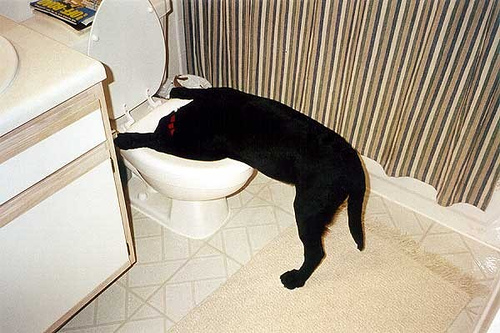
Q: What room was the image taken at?
A: It was taken at the bathroom.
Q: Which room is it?
A: It is a bathroom.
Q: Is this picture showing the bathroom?
A: Yes, it is showing the bathroom.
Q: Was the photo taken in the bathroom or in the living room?
A: It was taken at the bathroom.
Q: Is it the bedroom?
A: No, it is the bathroom.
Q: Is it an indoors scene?
A: Yes, it is indoors.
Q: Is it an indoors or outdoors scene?
A: It is indoors.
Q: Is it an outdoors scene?
A: No, it is indoors.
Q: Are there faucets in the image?
A: No, there are no faucets.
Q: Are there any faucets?
A: No, there are no faucets.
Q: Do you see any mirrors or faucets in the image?
A: No, there are no faucets or mirrors.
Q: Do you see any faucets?
A: No, there are no faucets.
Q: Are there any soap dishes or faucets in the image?
A: No, there are no faucets or soap dishes.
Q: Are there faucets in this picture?
A: No, there are no faucets.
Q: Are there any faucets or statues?
A: No, there are no faucets or statues.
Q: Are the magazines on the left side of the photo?
A: Yes, the magazines are on the left of the image.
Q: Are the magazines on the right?
A: No, the magazines are on the left of the image.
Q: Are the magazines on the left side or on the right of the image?
A: The magazines are on the left of the image.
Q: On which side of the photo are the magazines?
A: The magazines are on the left of the image.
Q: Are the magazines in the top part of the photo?
A: Yes, the magazines are in the top of the image.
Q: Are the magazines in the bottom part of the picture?
A: No, the magazines are in the top of the image.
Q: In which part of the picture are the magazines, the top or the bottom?
A: The magazines are in the top of the image.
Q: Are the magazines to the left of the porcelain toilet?
A: Yes, the magazines are to the left of the toilet.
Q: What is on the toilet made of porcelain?
A: The magazines are on the toilet.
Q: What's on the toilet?
A: The magazines are on the toilet.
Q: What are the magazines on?
A: The magazines are on the toilet.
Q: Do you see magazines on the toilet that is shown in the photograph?
A: Yes, there are magazines on the toilet.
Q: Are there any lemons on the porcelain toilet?
A: No, there are magazines on the toilet.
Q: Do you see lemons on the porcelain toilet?
A: No, there are magazines on the toilet.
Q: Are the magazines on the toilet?
A: Yes, the magazines are on the toilet.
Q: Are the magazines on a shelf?
A: No, the magazines are on the toilet.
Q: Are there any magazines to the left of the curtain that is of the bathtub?
A: Yes, there are magazines to the left of the curtain.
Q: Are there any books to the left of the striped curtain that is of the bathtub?
A: No, there are magazines to the left of the curtain.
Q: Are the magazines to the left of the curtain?
A: Yes, the magazines are to the left of the curtain.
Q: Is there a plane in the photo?
A: No, there are no airplanes.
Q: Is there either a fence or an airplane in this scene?
A: No, there are no airplanes or fences.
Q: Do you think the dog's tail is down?
A: Yes, the tail is down.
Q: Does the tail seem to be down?
A: Yes, the tail is down.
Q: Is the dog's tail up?
A: No, the tail is down.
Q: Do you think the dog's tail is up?
A: No, the tail is down.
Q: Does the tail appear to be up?
A: No, the tail is down.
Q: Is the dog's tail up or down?
A: The tail is down.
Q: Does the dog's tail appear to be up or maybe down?
A: The tail is down.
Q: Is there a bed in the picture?
A: No, there are no beds.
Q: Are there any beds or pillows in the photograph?
A: No, there are no beds or pillows.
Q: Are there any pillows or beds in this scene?
A: No, there are no beds or pillows.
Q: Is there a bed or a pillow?
A: No, there are no beds or pillows.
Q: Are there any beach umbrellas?
A: No, there are no beach umbrellas.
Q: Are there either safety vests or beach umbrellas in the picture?
A: No, there are no beach umbrellas or safety vests.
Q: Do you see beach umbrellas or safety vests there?
A: No, there are no beach umbrellas or safety vests.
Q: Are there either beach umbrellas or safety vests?
A: No, there are no beach umbrellas or safety vests.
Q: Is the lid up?
A: Yes, the lid is up.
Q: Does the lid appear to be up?
A: Yes, the lid is up.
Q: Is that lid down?
A: No, the lid is up.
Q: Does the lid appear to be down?
A: No, the lid is up.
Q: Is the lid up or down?
A: The lid is up.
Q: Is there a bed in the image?
A: No, there are no beds.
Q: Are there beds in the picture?
A: No, there are no beds.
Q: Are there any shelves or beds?
A: No, there are no beds or shelves.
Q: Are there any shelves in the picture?
A: No, there are no shelves.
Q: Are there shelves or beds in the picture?
A: No, there are no shelves or beds.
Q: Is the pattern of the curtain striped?
A: Yes, the curtain is striped.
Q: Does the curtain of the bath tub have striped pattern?
A: Yes, the curtain is striped.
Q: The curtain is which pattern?
A: The curtain is striped.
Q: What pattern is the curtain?
A: The curtain is striped.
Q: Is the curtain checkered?
A: No, the curtain is striped.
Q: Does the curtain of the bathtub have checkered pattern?
A: No, the curtain is striped.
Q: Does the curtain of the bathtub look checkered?
A: No, the curtain is striped.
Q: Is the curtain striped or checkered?
A: The curtain is striped.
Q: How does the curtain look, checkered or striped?
A: The curtain is striped.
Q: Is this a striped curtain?
A: Yes, this is a striped curtain.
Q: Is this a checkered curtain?
A: No, this is a striped curtain.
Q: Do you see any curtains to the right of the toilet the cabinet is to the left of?
A: Yes, there is a curtain to the right of the toilet.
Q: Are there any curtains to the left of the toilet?
A: No, the curtain is to the right of the toilet.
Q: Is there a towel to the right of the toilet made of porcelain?
A: No, there is a curtain to the right of the toilet.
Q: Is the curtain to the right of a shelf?
A: No, the curtain is to the right of the toilet.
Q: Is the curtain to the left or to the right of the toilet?
A: The curtain is to the right of the toilet.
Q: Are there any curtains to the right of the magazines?
A: Yes, there is a curtain to the right of the magazines.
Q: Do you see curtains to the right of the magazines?
A: Yes, there is a curtain to the right of the magazines.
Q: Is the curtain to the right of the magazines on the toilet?
A: Yes, the curtain is to the right of the magazines.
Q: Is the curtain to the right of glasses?
A: No, the curtain is to the right of the magazines.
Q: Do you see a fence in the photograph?
A: No, there are no fences.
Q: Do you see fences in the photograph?
A: No, there are no fences.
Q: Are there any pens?
A: No, there are no pens.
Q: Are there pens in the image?
A: No, there are no pens.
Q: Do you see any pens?
A: No, there are no pens.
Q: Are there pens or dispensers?
A: No, there are no pens or dispensers.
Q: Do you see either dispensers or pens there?
A: No, there are no pens or dispensers.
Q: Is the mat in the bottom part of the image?
A: Yes, the mat is in the bottom of the image.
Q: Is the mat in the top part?
A: No, the mat is in the bottom of the image.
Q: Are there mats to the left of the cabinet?
A: No, the mat is to the right of the cabinet.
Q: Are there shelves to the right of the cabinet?
A: No, there is a mat to the right of the cabinet.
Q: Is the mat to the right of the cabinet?
A: Yes, the mat is to the right of the cabinet.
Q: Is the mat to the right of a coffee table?
A: No, the mat is to the right of the cabinet.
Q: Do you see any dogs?
A: Yes, there is a dog.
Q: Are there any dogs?
A: Yes, there is a dog.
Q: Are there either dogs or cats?
A: Yes, there is a dog.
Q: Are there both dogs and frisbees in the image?
A: No, there is a dog but no frisbees.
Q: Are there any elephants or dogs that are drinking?
A: Yes, the dog is drinking.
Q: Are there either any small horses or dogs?
A: Yes, there is a small dog.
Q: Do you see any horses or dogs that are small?
A: Yes, the dog is small.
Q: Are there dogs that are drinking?
A: Yes, there is a dog that is drinking.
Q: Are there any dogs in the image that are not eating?
A: Yes, there is a dog that is drinking.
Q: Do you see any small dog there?
A: Yes, there is a small dog.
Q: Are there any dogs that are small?
A: Yes, there is a dog that is small.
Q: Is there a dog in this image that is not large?
A: Yes, there is a small dog.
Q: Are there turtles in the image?
A: No, there are no turtles.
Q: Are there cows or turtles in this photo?
A: No, there are no turtles or cows.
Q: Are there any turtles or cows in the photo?
A: No, there are no turtles or cows.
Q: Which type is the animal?
A: The animal is a dog.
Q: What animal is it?
A: The animal is a dog.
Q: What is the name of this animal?
A: This is a dog.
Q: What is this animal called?
A: This is a dog.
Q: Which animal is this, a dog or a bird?
A: This is a dog.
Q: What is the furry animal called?
A: The animal is a dog.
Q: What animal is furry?
A: The animal is a dog.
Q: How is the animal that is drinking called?
A: The animal is a dog.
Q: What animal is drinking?
A: The animal is a dog.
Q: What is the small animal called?
A: The animal is a dog.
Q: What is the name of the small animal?
A: The animal is a dog.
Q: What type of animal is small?
A: The animal is a dog.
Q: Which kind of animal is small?
A: The animal is a dog.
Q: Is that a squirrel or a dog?
A: That is a dog.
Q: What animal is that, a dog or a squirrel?
A: That is a dog.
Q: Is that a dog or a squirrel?
A: That is a dog.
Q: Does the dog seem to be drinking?
A: Yes, the dog is drinking.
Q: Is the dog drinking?
A: Yes, the dog is drinking.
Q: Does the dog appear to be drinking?
A: Yes, the dog is drinking.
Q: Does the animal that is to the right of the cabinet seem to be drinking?
A: Yes, the dog is drinking.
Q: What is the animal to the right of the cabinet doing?
A: The dog is drinking.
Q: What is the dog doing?
A: The dog is drinking.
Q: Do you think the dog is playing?
A: No, the dog is drinking.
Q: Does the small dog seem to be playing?
A: No, the dog is drinking.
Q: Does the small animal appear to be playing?
A: No, the dog is drinking.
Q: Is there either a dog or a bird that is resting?
A: No, there is a dog but it is drinking.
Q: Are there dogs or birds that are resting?
A: No, there is a dog but it is drinking.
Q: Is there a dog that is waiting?
A: No, there is a dog but it is drinking.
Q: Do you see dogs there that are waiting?
A: No, there is a dog but it is drinking.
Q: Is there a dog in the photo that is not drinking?
A: No, there is a dog but it is drinking.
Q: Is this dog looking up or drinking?
A: The dog is drinking.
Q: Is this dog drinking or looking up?
A: The dog is drinking.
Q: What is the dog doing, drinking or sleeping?
A: The dog is drinking.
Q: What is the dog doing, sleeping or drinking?
A: The dog is drinking.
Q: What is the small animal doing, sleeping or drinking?
A: The dog is drinking.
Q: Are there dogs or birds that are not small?
A: No, there is a dog but it is small.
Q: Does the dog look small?
A: Yes, the dog is small.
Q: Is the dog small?
A: Yes, the dog is small.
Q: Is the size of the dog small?
A: Yes, the dog is small.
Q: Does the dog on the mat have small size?
A: Yes, the dog is small.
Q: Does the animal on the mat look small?
A: Yes, the dog is small.